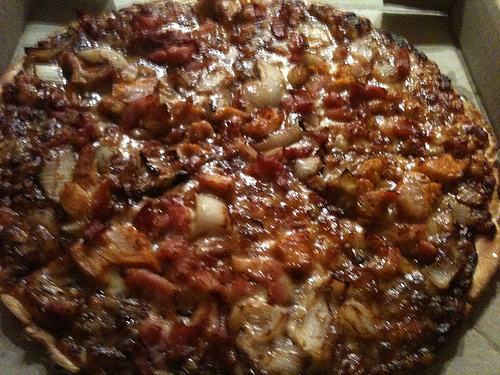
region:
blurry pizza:
[1, 3, 496, 371]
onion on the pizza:
[31, 60, 73, 95]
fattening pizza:
[1, 1, 498, 371]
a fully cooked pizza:
[6, 3, 495, 368]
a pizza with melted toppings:
[6, 5, 493, 374]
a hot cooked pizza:
[6, 6, 495, 369]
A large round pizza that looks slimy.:
[1, 1, 497, 371]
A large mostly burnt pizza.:
[0, 0, 495, 370]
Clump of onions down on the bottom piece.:
[230, 280, 330, 370]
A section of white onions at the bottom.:
[240, 276, 332, 367]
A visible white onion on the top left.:
[30, 60, 65, 82]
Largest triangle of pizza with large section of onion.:
[2, 160, 468, 371]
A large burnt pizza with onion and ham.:
[0, 0, 495, 370]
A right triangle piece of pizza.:
[275, 32, 495, 302]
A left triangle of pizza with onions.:
[1, 23, 241, 290]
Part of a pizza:
[153, 252, 357, 372]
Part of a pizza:
[40, 170, 174, 371]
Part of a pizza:
[261, 124, 491, 326]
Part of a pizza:
[137, 91, 287, 368]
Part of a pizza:
[10, 36, 197, 193]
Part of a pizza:
[87, 0, 415, 162]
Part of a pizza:
[24, 60, 199, 368]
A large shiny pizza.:
[7, 4, 499, 373]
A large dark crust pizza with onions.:
[1, 4, 498, 370]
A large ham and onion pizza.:
[6, 9, 498, 374]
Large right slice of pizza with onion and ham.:
[269, 27, 499, 303]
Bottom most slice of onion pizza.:
[5, 149, 463, 374]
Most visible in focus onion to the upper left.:
[35, 61, 66, 86]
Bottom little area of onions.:
[238, 294, 333, 374]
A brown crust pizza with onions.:
[0, 3, 498, 373]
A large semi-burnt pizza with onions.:
[4, 10, 499, 372]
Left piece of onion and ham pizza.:
[1, 53, 238, 295]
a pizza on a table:
[10, 23, 497, 355]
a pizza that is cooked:
[17, 5, 499, 337]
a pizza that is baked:
[25, 18, 432, 373]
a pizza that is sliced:
[21, 24, 498, 359]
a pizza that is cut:
[14, 22, 496, 357]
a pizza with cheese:
[62, 37, 497, 347]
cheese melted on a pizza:
[28, 11, 473, 370]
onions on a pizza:
[183, 188, 246, 246]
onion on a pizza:
[34, 148, 85, 186]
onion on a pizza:
[67, 37, 132, 70]